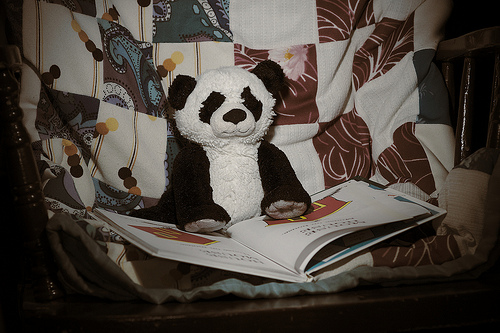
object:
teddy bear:
[130, 59, 313, 235]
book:
[85, 174, 448, 287]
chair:
[0, 1, 499, 332]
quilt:
[14, 0, 499, 306]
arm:
[2, 44, 50, 263]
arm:
[434, 26, 499, 168]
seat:
[13, 274, 499, 332]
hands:
[173, 204, 232, 234]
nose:
[223, 110, 246, 122]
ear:
[167, 73, 198, 110]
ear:
[250, 59, 288, 94]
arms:
[172, 144, 211, 210]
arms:
[258, 139, 302, 187]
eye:
[246, 98, 258, 110]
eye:
[208, 99, 219, 109]